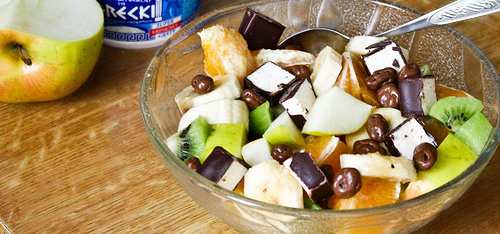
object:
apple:
[0, 1, 103, 106]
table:
[1, 0, 497, 231]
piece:
[198, 25, 257, 81]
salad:
[171, 17, 497, 211]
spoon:
[282, 1, 499, 50]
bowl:
[136, 2, 500, 233]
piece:
[167, 117, 207, 160]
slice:
[304, 87, 374, 136]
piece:
[242, 160, 304, 208]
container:
[99, 1, 199, 49]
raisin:
[190, 75, 215, 94]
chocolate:
[240, 8, 287, 49]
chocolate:
[413, 140, 439, 170]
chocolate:
[330, 166, 362, 200]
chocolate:
[366, 69, 399, 87]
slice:
[334, 176, 401, 208]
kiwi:
[432, 95, 484, 128]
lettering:
[104, 3, 155, 20]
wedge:
[268, 109, 304, 146]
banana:
[312, 43, 344, 93]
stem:
[15, 45, 34, 66]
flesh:
[1, 0, 104, 42]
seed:
[460, 113, 466, 120]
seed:
[447, 124, 453, 130]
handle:
[360, 1, 499, 47]